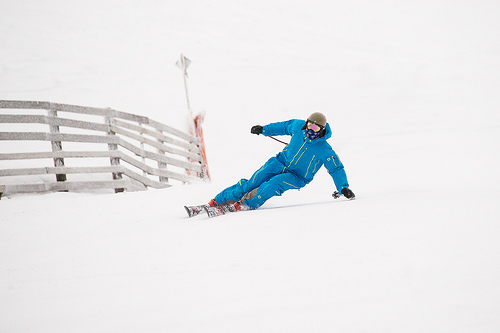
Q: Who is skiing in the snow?
A: The person.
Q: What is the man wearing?
A: Snow gear.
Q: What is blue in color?
A: The snow outfit.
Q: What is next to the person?
A: A fence.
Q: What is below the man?
A: Skis.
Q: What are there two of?
A: Skis.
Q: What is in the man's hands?
A: Poles.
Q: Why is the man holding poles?
A: Speed.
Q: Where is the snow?
A: On the ground.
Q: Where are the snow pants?
A: On the man's legs.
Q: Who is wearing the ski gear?
A: The skier.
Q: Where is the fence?
A: On the side of the trail.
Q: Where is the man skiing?
A: On the snow.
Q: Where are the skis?
A: On the ground.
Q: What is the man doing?
A: Skiing.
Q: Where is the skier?
A: On the slop.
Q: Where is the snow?
A: On the grounhd.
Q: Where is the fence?
A: By the skier.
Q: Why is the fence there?
A: To keep on the traiol.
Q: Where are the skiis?
A: On the skier's feet.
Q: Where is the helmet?
A: On the man's head.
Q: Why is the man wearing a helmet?
A: Safety.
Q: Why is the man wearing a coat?
A: Cold.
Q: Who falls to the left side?
A: A skier.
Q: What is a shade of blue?
A: A snow suit.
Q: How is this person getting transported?
A: Skies.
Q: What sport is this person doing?
A: Skiing.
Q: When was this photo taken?
A: During the daytime.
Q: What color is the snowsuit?
A: Blue.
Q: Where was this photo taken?
A: On a ski slope.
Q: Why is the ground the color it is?
A: It's covered in snow.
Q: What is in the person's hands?
A: Ski Poles.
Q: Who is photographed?
A: A skier.